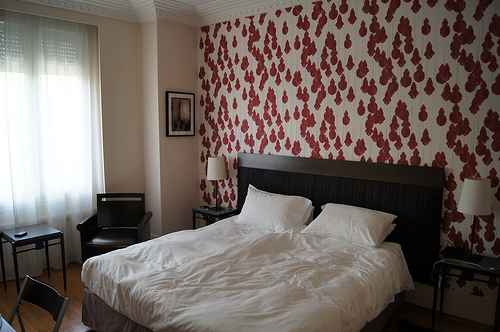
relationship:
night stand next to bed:
[192, 204, 237, 230] [92, 200, 437, 330]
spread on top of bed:
[81, 214, 417, 332] [93, 157, 412, 308]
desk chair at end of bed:
[6, 272, 72, 329] [77, 151, 445, 329]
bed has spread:
[92, 189, 390, 330] [192, 219, 327, 270]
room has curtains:
[9, 5, 488, 327] [5, 12, 105, 243]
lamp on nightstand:
[201, 143, 238, 218] [190, 203, 230, 230]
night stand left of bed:
[190, 205, 236, 228] [77, 151, 445, 329]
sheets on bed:
[80, 215, 416, 329] [77, 151, 445, 329]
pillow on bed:
[256, 196, 317, 233] [77, 151, 445, 329]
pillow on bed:
[233, 184, 312, 234] [77, 151, 445, 329]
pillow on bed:
[325, 215, 401, 248] [77, 151, 445, 329]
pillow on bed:
[308, 198, 392, 248] [77, 151, 445, 329]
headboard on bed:
[235, 148, 442, 279] [77, 151, 445, 329]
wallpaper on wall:
[190, 2, 498, 259] [199, 0, 499, 255]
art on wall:
[163, 89, 195, 138] [150, 17, 196, 233]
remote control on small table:
[15, 229, 30, 238] [0, 221, 64, 246]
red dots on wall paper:
[298, 54, 403, 126] [202, 1, 497, 253]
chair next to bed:
[76, 191, 151, 262] [77, 151, 445, 329]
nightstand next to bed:
[189, 202, 238, 228] [77, 151, 445, 329]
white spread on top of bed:
[80, 213, 412, 330] [77, 151, 445, 329]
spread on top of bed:
[82, 191, 409, 329] [73, 181, 429, 330]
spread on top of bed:
[81, 214, 417, 332] [54, 141, 471, 329]